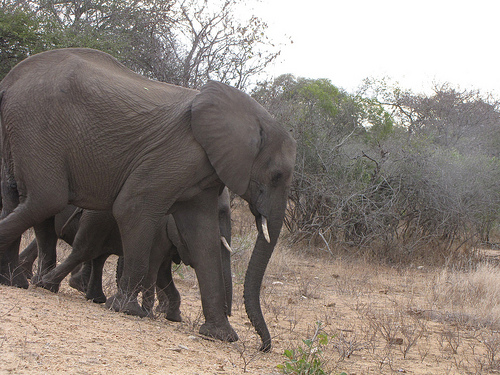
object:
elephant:
[0, 47, 295, 352]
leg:
[113, 181, 188, 296]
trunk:
[241, 196, 289, 354]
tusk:
[261, 215, 271, 244]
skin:
[45, 108, 184, 188]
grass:
[306, 245, 409, 341]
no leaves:
[312, 177, 444, 288]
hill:
[0, 180, 349, 375]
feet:
[198, 319, 240, 342]